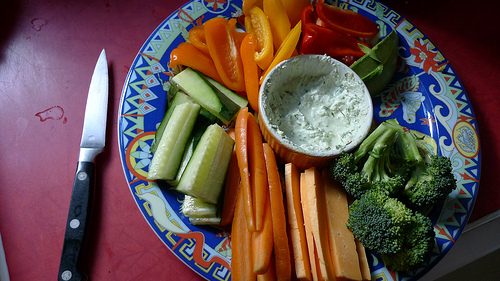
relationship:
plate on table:
[127, 3, 477, 272] [1, 1, 498, 279]